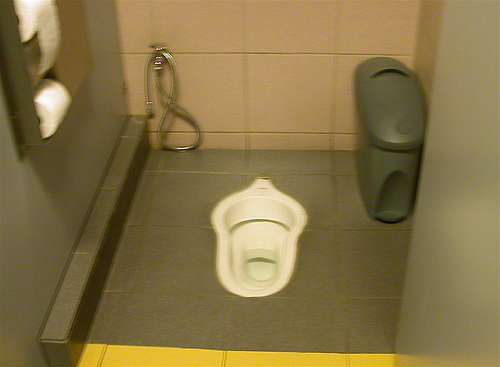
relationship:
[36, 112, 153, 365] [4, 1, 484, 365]
baseboard in toilet stall